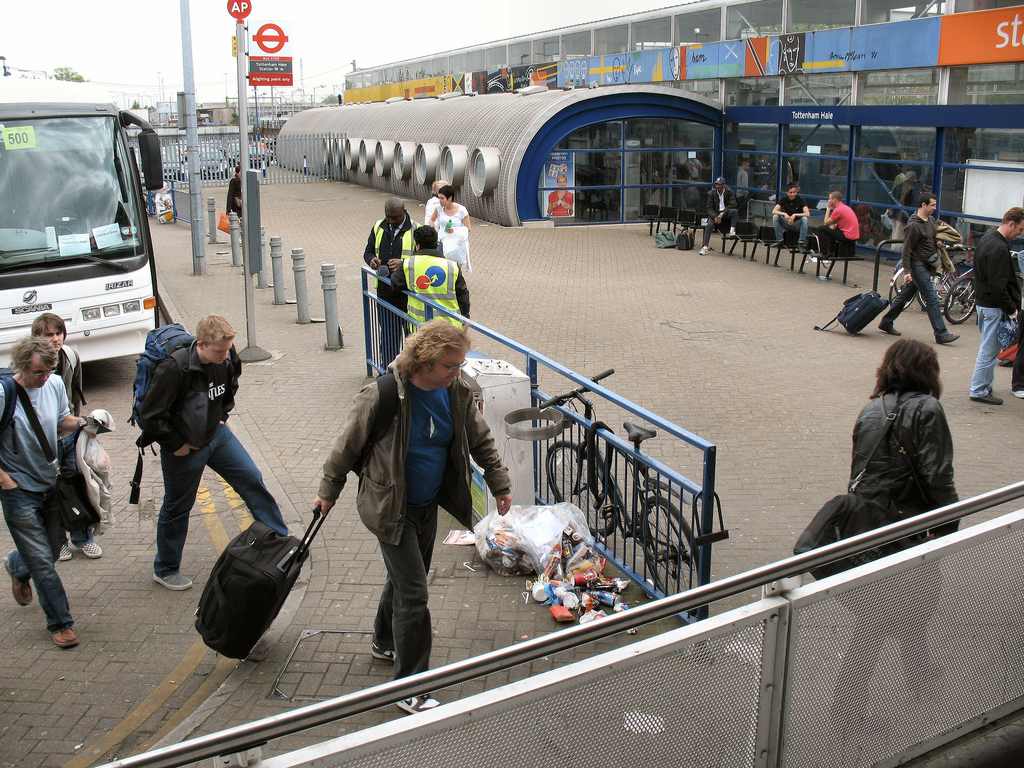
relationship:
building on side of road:
[256, 67, 760, 236] [174, 128, 982, 653]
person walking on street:
[8, 342, 101, 632] [19, 353, 473, 753]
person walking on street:
[14, 329, 90, 531] [17, 337, 530, 761]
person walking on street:
[138, 298, 313, 595] [19, 351, 529, 730]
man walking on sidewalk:
[305, 316, 516, 713] [36, 443, 676, 742]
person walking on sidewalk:
[764, 312, 978, 730] [470, 251, 967, 759]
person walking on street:
[877, 184, 955, 362] [529, 186, 1003, 474]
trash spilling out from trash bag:
[527, 521, 625, 638] [454, 482, 599, 586]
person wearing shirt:
[138, 298, 313, 595] [140, 343, 244, 467]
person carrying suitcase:
[823, 336, 962, 736] [788, 482, 942, 621]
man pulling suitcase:
[294, 287, 534, 707] [130, 458, 377, 677]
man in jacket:
[294, 287, 534, 707] [274, 348, 525, 549]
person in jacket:
[139, 311, 291, 592] [125, 309, 257, 487]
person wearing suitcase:
[139, 311, 291, 592] [130, 318, 208, 461]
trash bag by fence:
[436, 490, 631, 594] [350, 237, 722, 611]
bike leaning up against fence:
[514, 361, 711, 653] [357, 262, 716, 625]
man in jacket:
[689, 171, 759, 271] [698, 177, 740, 238]